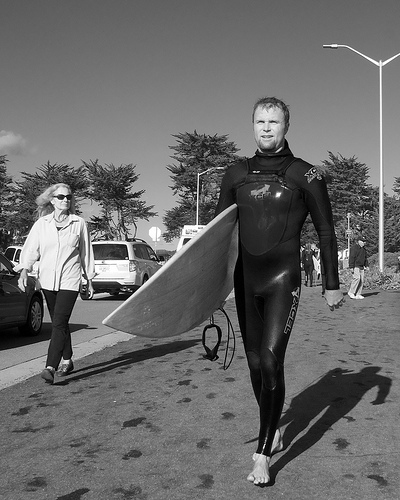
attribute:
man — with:
[227, 88, 364, 495]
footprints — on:
[328, 431, 352, 456]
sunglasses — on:
[49, 191, 74, 202]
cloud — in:
[6, 122, 39, 162]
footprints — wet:
[12, 303, 387, 496]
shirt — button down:
[18, 212, 96, 289]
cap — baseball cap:
[356, 234, 369, 243]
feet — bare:
[249, 431, 281, 487]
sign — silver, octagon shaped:
[147, 228, 160, 240]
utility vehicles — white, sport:
[76, 237, 164, 301]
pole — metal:
[377, 58, 385, 274]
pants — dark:
[39, 289, 81, 373]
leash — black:
[203, 306, 237, 369]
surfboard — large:
[104, 200, 240, 336]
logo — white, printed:
[281, 286, 300, 335]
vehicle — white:
[79, 237, 159, 299]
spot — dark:
[196, 473, 213, 491]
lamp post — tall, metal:
[323, 42, 398, 276]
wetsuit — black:
[216, 141, 339, 458]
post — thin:
[377, 58, 384, 271]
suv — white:
[77, 237, 165, 300]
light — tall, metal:
[319, 40, 399, 274]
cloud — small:
[0, 127, 38, 158]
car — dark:
[0, 248, 46, 338]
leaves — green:
[319, 148, 369, 188]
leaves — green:
[364, 218, 377, 236]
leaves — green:
[21, 160, 90, 201]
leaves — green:
[14, 206, 31, 223]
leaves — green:
[119, 201, 158, 221]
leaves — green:
[159, 205, 196, 221]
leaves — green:
[159, 207, 179, 230]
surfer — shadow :
[180, 86, 387, 477]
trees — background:
[161, 121, 387, 235]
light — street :
[310, 25, 387, 269]